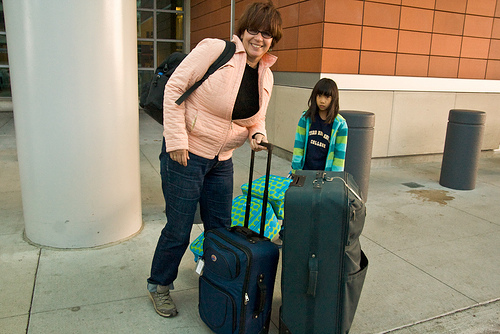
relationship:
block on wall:
[393, 50, 431, 76] [365, 51, 429, 130]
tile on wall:
[336, 6, 428, 76] [382, 50, 453, 82]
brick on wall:
[319, 19, 362, 50] [319, 6, 461, 78]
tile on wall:
[396, 3, 436, 30] [323, 0, 498, 84]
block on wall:
[359, 21, 401, 54] [427, 50, 453, 130]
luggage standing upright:
[277, 167, 368, 334] [324, 189, 390, 309]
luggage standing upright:
[277, 167, 368, 334] [311, 221, 377, 334]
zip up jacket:
[223, 74, 240, 171] [163, 42, 275, 164]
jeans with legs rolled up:
[145, 174, 292, 318] [143, 241, 193, 313]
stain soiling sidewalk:
[407, 182, 454, 211] [368, 155, 498, 332]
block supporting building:
[319, 20, 364, 53] [279, 0, 499, 97]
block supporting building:
[359, 21, 401, 54] [279, 0, 499, 97]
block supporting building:
[395, 28, 432, 57] [279, 0, 499, 97]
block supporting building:
[357, 49, 397, 76] [279, 0, 499, 97]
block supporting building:
[393, 50, 431, 76] [279, 0, 499, 97]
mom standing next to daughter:
[138, 2, 287, 317] [279, 66, 364, 193]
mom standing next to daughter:
[138, 2, 287, 317] [286, 61, 356, 190]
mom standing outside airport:
[138, 2, 287, 317] [2, 1, 484, 331]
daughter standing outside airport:
[291, 76, 347, 180] [2, 1, 484, 331]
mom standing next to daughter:
[138, 2, 287, 317] [291, 76, 347, 180]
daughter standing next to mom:
[291, 76, 347, 180] [142, 2, 286, 317]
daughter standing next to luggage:
[291, 76, 347, 180] [277, 167, 369, 332]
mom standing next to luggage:
[142, 2, 286, 317] [277, 167, 369, 332]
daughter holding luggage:
[291, 76, 347, 180] [189, 171, 292, 267]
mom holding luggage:
[142, 2, 286, 317] [198, 135, 279, 332]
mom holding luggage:
[138, 2, 287, 317] [198, 135, 279, 332]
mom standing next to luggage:
[138, 2, 287, 317] [277, 167, 369, 332]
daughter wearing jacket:
[291, 76, 347, 180] [290, 112, 347, 174]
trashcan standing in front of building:
[437, 97, 492, 189] [5, 2, 492, 154]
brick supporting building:
[319, 19, 362, 50] [2, 1, 484, 170]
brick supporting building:
[318, 45, 361, 74] [2, 1, 484, 170]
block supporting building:
[357, 49, 397, 76] [2, 1, 484, 170]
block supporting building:
[359, 21, 401, 54] [2, 1, 484, 170]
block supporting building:
[395, 28, 432, 57] [2, 1, 484, 170]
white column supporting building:
[1, 3, 141, 248] [138, 2, 498, 163]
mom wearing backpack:
[138, 2, 287, 317] [142, 50, 181, 116]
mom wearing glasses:
[138, 2, 287, 317] [242, 22, 275, 39]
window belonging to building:
[158, 12, 188, 39] [2, 1, 484, 170]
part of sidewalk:
[371, 150, 496, 332] [1, 155, 498, 332]